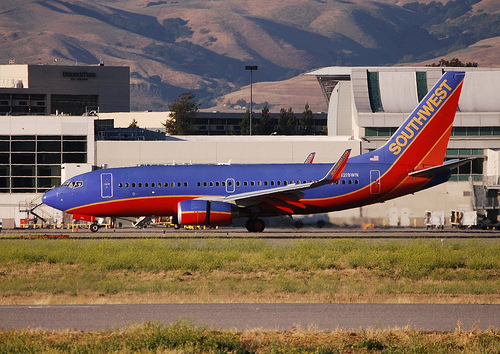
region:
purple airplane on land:
[13, 157, 190, 238]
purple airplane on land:
[27, 148, 248, 298]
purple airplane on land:
[20, 87, 334, 292]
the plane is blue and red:
[31, 119, 468, 259]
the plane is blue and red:
[81, 128, 407, 207]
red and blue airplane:
[39, 67, 487, 230]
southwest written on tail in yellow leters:
[386, 75, 454, 165]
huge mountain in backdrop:
[132, 18, 393, 98]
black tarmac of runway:
[26, 296, 497, 338]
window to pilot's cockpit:
[57, 176, 86, 193]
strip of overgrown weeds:
[32, 242, 440, 268]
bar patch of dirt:
[26, 257, 326, 282]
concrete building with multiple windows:
[2, 112, 102, 219]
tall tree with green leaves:
[162, 83, 200, 140]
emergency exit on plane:
[367, 162, 383, 197]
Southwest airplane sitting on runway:
[18, 50, 473, 258]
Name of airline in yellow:
[365, 63, 470, 178]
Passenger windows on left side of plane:
[25, 155, 386, 195]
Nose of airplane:
[27, 170, 68, 225]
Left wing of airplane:
[181, 127, 383, 268]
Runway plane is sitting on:
[0, 210, 496, 253]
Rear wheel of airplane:
[227, 212, 282, 238]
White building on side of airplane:
[0, 45, 487, 230]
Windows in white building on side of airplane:
[5, 98, 110, 199]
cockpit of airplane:
[51, 172, 101, 200]